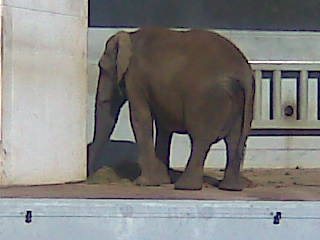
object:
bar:
[296, 70, 308, 121]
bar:
[272, 70, 281, 120]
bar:
[253, 69, 262, 120]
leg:
[156, 130, 174, 169]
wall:
[0, 8, 91, 189]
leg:
[129, 99, 171, 186]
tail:
[233, 76, 253, 165]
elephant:
[86, 26, 255, 190]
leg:
[218, 137, 243, 190]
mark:
[25, 211, 32, 224]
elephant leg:
[175, 136, 217, 190]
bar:
[249, 119, 319, 129]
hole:
[284, 106, 293, 116]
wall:
[88, 26, 320, 172]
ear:
[115, 31, 132, 84]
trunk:
[86, 68, 127, 178]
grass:
[87, 163, 147, 193]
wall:
[0, 198, 320, 240]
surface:
[0, 0, 89, 189]